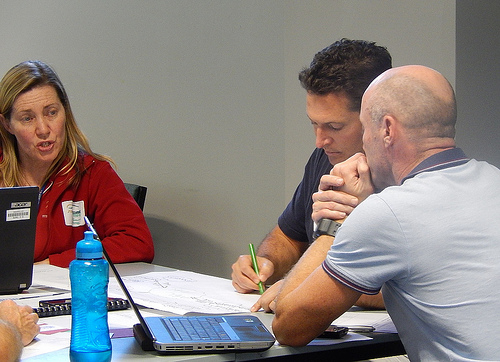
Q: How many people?
A: 3.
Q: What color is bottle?
A: Blue.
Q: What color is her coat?
A: Red.